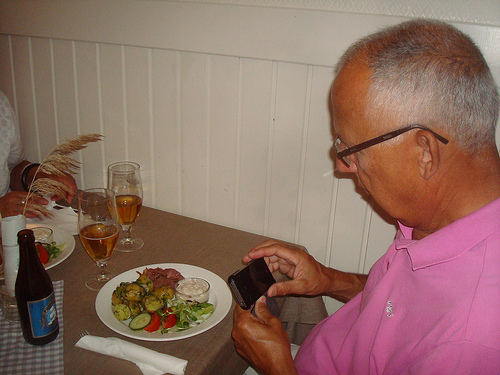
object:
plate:
[0, 222, 78, 280]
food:
[30, 222, 69, 264]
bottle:
[9, 221, 75, 342]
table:
[0, 159, 317, 373]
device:
[226, 257, 278, 311]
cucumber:
[127, 312, 153, 332]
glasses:
[72, 186, 122, 290]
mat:
[2, 276, 65, 373]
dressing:
[175, 275, 212, 303]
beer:
[77, 221, 119, 259]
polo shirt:
[291, 195, 499, 375]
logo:
[384, 298, 395, 321]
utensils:
[75, 328, 91, 342]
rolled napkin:
[60, 333, 194, 374]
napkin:
[73, 332, 189, 375]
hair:
[331, 18, 499, 159]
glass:
[75, 186, 124, 290]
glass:
[106, 160, 148, 252]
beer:
[13, 227, 61, 346]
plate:
[96, 261, 233, 343]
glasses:
[327, 122, 453, 171]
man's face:
[323, 70, 403, 224]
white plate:
[91, 262, 234, 342]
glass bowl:
[174, 275, 211, 305]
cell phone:
[227, 256, 281, 309]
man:
[307, 17, 500, 375]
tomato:
[159, 309, 175, 329]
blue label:
[22, 288, 64, 340]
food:
[104, 261, 229, 344]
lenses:
[326, 135, 358, 172]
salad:
[108, 265, 218, 336]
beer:
[109, 191, 141, 224]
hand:
[227, 289, 298, 373]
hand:
[242, 239, 331, 302]